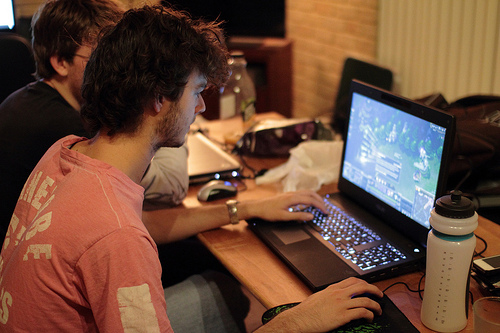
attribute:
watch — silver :
[225, 194, 247, 236]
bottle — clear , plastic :
[218, 48, 256, 160]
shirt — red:
[0, 135, 173, 331]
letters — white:
[3, 172, 58, 322]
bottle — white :
[420, 189, 480, 331]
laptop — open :
[246, 78, 457, 291]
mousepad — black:
[322, 273, 387, 323]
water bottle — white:
[412, 186, 497, 332]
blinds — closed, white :
[376, 1, 498, 94]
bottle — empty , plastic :
[221, 60, 285, 137]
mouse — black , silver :
[193, 178, 243, 203]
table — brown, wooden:
[179, 154, 499, 331]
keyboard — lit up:
[288, 190, 413, 274]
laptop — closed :
[187, 130, 241, 185]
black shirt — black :
[0, 80, 85, 225]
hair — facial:
[85, 17, 170, 139]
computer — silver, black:
[250, 70, 481, 252]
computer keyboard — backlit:
[283, 193, 410, 275]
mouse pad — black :
[350, 275, 415, 331]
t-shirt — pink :
[1, 131, 175, 331]